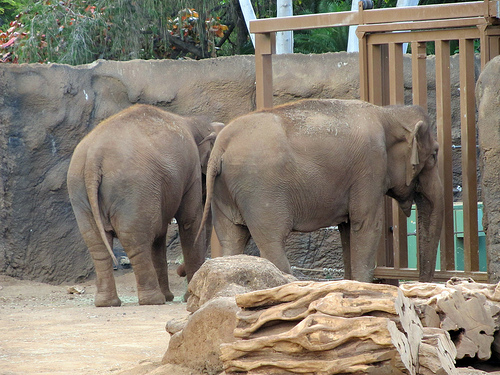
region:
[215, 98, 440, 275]
Elephant facing fence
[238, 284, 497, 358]
Fake logs in elephant cage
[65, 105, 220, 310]
Second elephant in cage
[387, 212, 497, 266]
Water outside fence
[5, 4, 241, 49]
Grass and weeds above cage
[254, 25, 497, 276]
Fence holding elephants in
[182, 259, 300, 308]
Large rock in elephant cage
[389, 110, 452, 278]
Elephant trunk and mouth open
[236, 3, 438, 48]
White birch tree trunks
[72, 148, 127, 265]
Elephant tail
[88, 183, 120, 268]
thick gray tail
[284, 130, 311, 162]
wrinkle gray skin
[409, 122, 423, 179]
floppy elephant ear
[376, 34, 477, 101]
brown wooden planks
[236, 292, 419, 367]
old brown tree stump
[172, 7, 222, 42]
orange fruit in a tree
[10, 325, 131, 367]
beige sand on the ground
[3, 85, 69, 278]
gray stone wall next to elephant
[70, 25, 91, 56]
dried tree branches there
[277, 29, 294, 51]
white bark on a tree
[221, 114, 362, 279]
the elephant is brown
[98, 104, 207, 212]
the elephant is brown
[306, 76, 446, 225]
the elephant is brown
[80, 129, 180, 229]
the elephant is brown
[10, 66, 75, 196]
a brown and gray stone wall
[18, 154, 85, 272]
a brown and gray stone wall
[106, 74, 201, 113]
a brown and gray stone wall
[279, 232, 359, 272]
a brown and gray stone wall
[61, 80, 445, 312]
two elephants next to each other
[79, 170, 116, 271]
long elephant tail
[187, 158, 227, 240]
long elephant tail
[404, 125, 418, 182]
floppy elephant ear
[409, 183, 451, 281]
long grey elephant trunk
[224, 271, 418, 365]
large log in front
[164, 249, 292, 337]
large boulder behind log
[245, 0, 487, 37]
wooden post on top of pieces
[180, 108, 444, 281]
elephant standing on ground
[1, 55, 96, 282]
large rock wall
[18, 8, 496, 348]
elephants inside enclosure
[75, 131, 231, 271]
curved elephant tails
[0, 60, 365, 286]
textured gray and brown wall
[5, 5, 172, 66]
drooping branches above wall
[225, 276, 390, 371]
wavy long lines on outside of log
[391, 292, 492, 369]
flat edges of cut trees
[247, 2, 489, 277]
brown gate with vertical bars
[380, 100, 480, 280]
elephant looking through gate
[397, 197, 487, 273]
green storage cabinet on other side of gate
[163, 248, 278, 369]
round rocks on ground